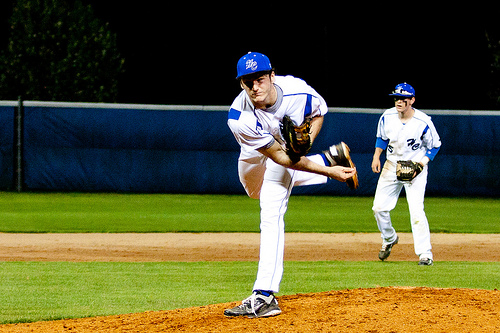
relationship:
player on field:
[370, 82, 440, 266] [0, 101, 498, 332]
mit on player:
[395, 160, 423, 182] [370, 82, 440, 266]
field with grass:
[0, 101, 498, 332] [1, 193, 498, 323]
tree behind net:
[1, 0, 128, 103] [0, 0, 498, 111]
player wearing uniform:
[370, 82, 440, 266] [372, 107, 441, 256]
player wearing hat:
[370, 82, 440, 266] [391, 82, 416, 98]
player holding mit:
[370, 82, 440, 266] [395, 160, 423, 182]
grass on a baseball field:
[1, 193, 498, 323] [0, 101, 498, 332]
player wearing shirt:
[370, 82, 440, 266] [377, 108, 441, 163]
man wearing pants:
[370, 82, 440, 266] [371, 161, 430, 255]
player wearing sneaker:
[223, 52, 357, 319] [224, 293, 280, 317]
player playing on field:
[370, 82, 440, 266] [0, 101, 498, 332]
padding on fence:
[0, 105, 496, 196] [0, 101, 496, 197]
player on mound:
[223, 52, 357, 319] [0, 285, 497, 332]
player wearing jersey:
[223, 52, 357, 319] [227, 75, 329, 157]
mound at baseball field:
[0, 285, 497, 332] [0, 101, 498, 332]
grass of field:
[1, 193, 498, 323] [0, 101, 498, 332]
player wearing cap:
[223, 52, 357, 319] [236, 52, 273, 79]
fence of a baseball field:
[0, 101, 496, 197] [0, 101, 498, 332]